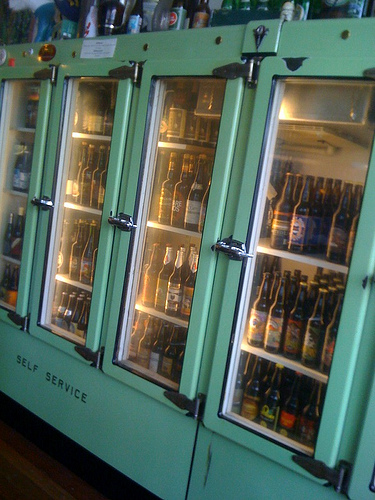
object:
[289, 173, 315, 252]
bottle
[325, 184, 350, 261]
bottle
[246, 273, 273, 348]
bottle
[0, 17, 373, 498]
cooler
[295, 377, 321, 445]
beer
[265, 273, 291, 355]
bottles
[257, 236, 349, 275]
shelf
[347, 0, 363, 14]
bottles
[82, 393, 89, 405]
letters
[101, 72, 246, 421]
door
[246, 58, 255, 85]
hinge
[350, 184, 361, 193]
lids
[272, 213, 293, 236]
labels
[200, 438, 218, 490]
scuff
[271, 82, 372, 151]
unit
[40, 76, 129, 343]
window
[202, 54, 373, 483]
door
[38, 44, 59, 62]
seal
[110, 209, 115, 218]
keyhold